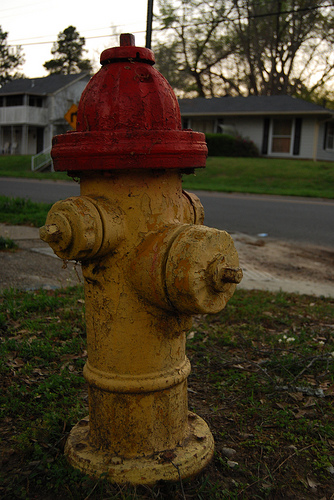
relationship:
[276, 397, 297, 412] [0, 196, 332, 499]
leaf on ground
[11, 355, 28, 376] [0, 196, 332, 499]
leaf on ground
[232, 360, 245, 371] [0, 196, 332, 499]
leaf on ground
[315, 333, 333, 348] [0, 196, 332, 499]
leaf laying on ground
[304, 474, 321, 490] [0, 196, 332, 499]
leaf laying on ground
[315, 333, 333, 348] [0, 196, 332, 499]
leaf on ground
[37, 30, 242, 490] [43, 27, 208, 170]
fire hydrant has top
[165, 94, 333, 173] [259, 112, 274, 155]
house has shutter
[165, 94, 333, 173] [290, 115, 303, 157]
house has shutter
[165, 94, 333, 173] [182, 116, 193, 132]
house has shutter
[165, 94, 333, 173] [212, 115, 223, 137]
house has shutter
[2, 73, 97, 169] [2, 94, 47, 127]
house has porch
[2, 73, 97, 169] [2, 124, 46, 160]
house has porch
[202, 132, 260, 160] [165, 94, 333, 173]
hedge bush in front of house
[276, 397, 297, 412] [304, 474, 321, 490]
leaf next to leaf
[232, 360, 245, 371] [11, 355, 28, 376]
leaf next to leaf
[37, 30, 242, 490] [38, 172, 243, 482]
fire hydrant has bottom portion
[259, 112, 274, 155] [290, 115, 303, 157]
shutter next to shutter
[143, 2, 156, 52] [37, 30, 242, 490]
utility pole behind fire hydrant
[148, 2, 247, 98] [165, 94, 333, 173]
tree behind house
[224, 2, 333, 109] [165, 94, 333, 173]
tree behind house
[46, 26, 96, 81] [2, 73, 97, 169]
tree behind house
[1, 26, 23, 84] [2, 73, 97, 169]
tree behind house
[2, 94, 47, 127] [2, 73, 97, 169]
porch in front of house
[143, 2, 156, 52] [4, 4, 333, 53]
utility pole has power line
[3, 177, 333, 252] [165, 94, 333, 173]
roadway in front of house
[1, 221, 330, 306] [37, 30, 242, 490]
sidewalk near fire hydrant